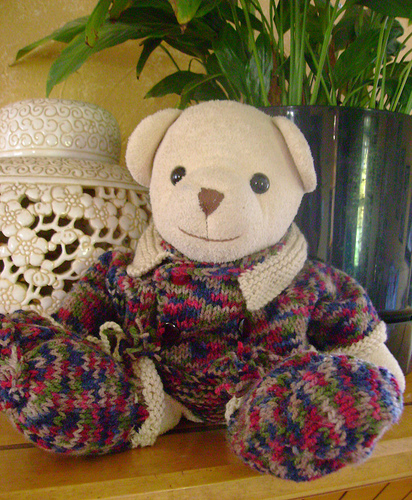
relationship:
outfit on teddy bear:
[0, 223, 406, 484] [154, 103, 387, 437]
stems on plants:
[50, 5, 395, 111] [21, 1, 401, 103]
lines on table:
[28, 449, 311, 500] [59, 458, 245, 495]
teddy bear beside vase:
[154, 103, 387, 437] [2, 99, 115, 312]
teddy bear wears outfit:
[154, 103, 387, 437] [0, 223, 406, 484]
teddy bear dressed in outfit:
[154, 103, 387, 437] [0, 223, 406, 484]